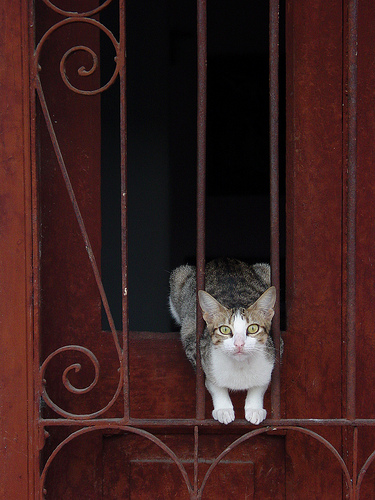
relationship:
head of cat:
[196, 287, 278, 361] [167, 256, 284, 424]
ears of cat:
[198, 285, 278, 322] [167, 256, 284, 424]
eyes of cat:
[217, 323, 260, 337] [167, 256, 284, 424]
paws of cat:
[212, 408, 268, 424] [167, 256, 284, 424]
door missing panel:
[0, 1, 374, 500] [130, 458, 253, 500]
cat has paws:
[167, 256, 284, 424] [212, 408, 268, 424]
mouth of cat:
[231, 351, 248, 358] [167, 256, 284, 424]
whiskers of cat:
[204, 342, 278, 361] [167, 256, 284, 424]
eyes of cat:
[218, 325, 232, 338] [167, 256, 284, 424]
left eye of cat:
[244, 323, 260, 335] [167, 256, 284, 424]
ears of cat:
[198, 289, 231, 325] [167, 256, 284, 424]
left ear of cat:
[252, 284, 277, 317] [167, 256, 284, 424]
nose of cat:
[233, 339, 244, 349] [167, 256, 284, 424]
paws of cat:
[212, 408, 235, 425] [167, 256, 284, 424]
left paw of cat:
[242, 407, 267, 426] [167, 256, 284, 424]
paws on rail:
[212, 408, 268, 424] [40, 418, 374, 427]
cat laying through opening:
[167, 256, 284, 424] [205, 48, 270, 418]